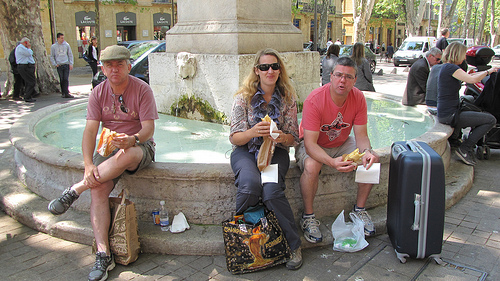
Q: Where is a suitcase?
A: On the ground.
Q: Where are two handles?
A: On the suitcase.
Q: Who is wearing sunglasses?
A: The woman.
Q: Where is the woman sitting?
A: On a water fountain.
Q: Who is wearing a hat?
A: Man sitting on left.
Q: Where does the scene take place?
A: At a city square.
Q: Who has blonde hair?
A: A woman sitting.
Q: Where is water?
A: In the fountain.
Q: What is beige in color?
A: Man's hat.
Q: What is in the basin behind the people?
A: Water.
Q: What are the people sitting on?
A: Fountain.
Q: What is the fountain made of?
A: Cement.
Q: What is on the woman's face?
A: Sunglasses.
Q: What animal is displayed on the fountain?
A: Lion.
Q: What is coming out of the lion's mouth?
A: Water.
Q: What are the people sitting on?
A: Fountain's lip.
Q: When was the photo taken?
A: Daytime.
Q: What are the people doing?
A: Eating.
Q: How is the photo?
A: Clear.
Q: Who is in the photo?
A: People.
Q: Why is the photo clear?
A: Its during the day.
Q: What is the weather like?
A: Sunny.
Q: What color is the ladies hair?
A: Blonde.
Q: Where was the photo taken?
A: Close to a fountain.